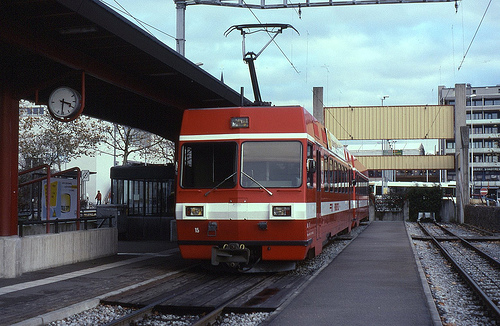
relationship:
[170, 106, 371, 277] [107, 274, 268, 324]
train on track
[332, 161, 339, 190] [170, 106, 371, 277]
window on train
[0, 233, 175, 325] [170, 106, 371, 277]
platform near train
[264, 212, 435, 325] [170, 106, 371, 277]
pavement near train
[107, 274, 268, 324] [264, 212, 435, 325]
track near pavement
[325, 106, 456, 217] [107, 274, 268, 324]
building near track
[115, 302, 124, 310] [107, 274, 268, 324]
rock near track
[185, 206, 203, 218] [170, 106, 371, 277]
light on train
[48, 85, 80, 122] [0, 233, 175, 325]
clock on platform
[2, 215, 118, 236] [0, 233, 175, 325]
railing on platform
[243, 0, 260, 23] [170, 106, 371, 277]
wire on top of train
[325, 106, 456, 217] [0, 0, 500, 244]
building in background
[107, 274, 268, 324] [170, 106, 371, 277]
track on which train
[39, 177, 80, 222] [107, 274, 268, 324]
sign by track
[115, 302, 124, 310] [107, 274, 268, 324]
rock surrounding track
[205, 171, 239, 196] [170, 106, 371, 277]
wiper on train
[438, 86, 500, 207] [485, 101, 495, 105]
building with window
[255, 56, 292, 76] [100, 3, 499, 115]
cloud i sky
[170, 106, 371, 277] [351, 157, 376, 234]
train has car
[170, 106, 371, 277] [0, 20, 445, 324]
train at station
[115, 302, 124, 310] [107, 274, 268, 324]
rock on track